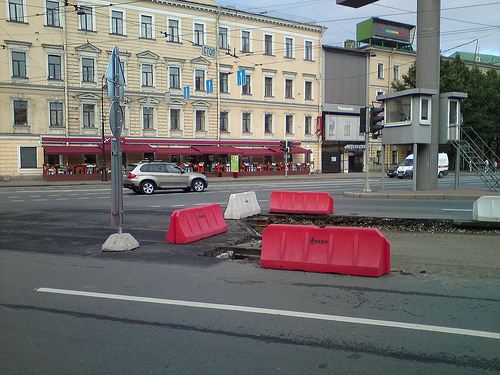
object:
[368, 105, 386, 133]
traffic stop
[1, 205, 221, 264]
road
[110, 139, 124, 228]
sign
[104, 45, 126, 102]
sign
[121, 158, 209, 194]
car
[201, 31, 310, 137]
wall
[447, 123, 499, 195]
stairs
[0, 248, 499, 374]
ground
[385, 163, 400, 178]
car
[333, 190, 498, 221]
roadway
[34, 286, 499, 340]
lane marker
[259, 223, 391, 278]
barrier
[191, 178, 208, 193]
wheel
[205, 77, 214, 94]
sign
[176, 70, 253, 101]
flags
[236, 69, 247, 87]
emblem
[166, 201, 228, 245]
road barriers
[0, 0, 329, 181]
building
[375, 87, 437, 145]
boxes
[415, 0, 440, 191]
pole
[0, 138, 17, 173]
beige brick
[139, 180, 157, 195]
wheel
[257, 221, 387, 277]
reflector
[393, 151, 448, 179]
white van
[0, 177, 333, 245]
road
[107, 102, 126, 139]
sign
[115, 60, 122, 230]
pole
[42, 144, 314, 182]
lobby